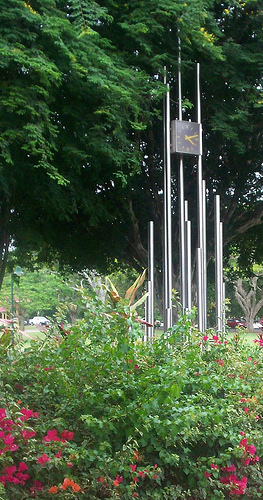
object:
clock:
[170, 118, 201, 157]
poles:
[214, 194, 221, 330]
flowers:
[21, 425, 35, 440]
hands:
[185, 134, 194, 145]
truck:
[44, 326, 54, 344]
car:
[225, 314, 247, 333]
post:
[10, 286, 14, 321]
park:
[0, 239, 173, 343]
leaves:
[30, 46, 39, 55]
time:
[184, 131, 200, 154]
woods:
[138, 235, 146, 255]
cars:
[0, 307, 22, 323]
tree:
[0, 0, 55, 296]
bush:
[221, 430, 233, 458]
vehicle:
[28, 313, 51, 328]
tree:
[27, 0, 154, 264]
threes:
[166, 218, 205, 306]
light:
[9, 267, 20, 325]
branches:
[45, 157, 68, 190]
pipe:
[145, 279, 153, 346]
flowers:
[200, 26, 204, 32]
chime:
[143, 165, 233, 352]